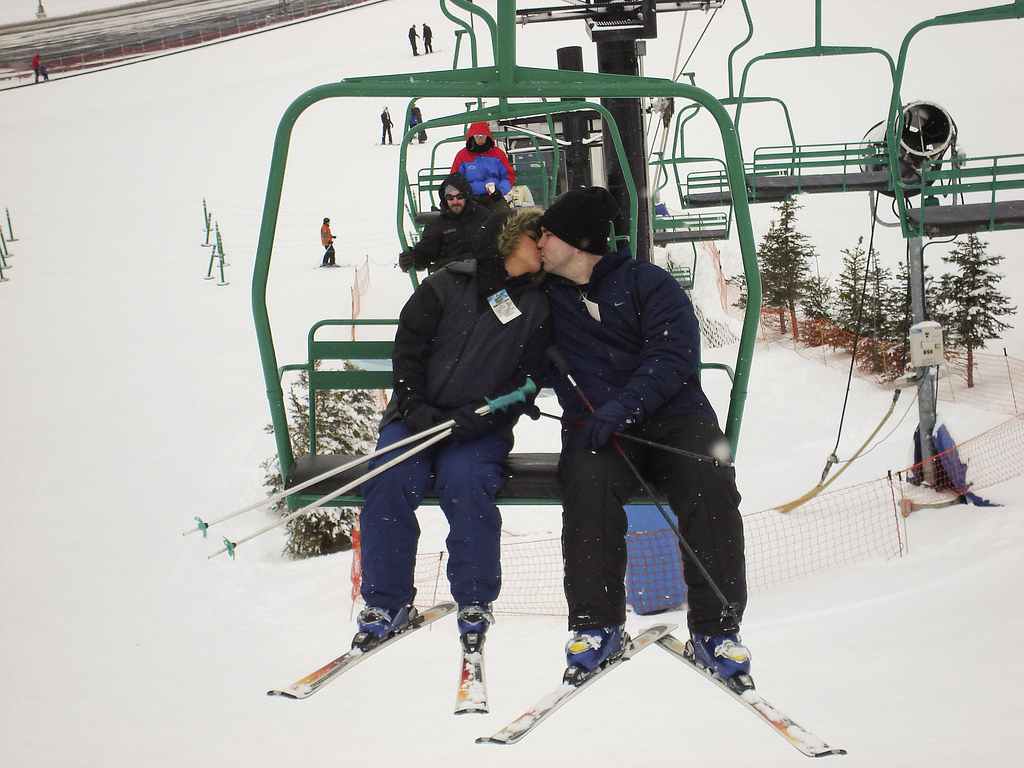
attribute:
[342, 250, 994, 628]
orange fence — orange 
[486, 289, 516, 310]
sticker — white and blue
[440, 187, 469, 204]
sunglasses — black 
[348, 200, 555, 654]
woman — blonde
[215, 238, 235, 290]
pole — green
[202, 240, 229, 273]
pole — green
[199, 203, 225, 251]
pole — green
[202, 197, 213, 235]
pole — green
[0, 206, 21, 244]
pole — green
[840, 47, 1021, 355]
chair — green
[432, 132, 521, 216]
jacket — red and blue 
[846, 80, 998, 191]
thing — big 